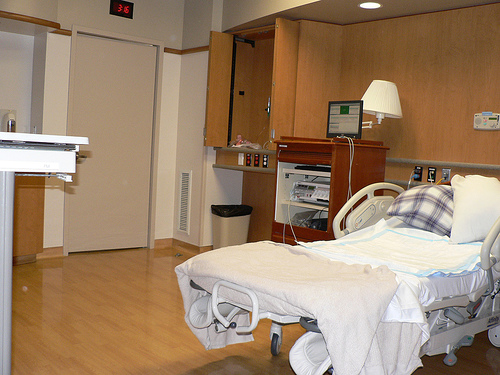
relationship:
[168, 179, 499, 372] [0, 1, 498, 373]
bed in room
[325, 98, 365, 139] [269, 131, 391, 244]
monitor on cabinet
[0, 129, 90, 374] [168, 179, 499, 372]
table for bed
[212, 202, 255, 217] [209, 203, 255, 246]
liner in trash can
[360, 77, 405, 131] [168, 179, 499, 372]
lamp beside bed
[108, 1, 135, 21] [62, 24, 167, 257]
clock above door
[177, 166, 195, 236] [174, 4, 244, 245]
air vent in wall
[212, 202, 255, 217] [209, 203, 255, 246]
garbage bag in garbage bin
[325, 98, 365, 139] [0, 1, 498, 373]
monitor in room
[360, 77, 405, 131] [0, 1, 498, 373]
lamp in room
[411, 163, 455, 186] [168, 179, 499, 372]
outlets behind bed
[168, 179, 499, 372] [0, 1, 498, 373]
bed for hospital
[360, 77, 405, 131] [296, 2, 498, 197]
lamp on wall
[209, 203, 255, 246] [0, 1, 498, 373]
trash can in room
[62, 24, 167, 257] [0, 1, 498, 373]
door to room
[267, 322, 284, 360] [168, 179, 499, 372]
wheel on bed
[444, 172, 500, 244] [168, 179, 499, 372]
pillow on bed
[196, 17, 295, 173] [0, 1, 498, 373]
storage in room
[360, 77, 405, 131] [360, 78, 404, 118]
lamp has shade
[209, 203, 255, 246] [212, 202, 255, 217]
trash can has bag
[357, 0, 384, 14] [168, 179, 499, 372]
light over bed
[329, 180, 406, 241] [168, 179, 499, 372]
rail on bed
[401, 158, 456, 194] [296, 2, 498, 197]
plugs and wires on wall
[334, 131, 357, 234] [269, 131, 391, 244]
wires hanging over table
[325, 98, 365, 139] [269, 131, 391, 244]
computer screen on table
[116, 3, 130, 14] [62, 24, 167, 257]
numbers above door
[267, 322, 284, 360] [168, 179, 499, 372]
wheel underneath bed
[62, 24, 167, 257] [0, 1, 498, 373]
door in room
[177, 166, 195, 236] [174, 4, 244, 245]
air vent on wall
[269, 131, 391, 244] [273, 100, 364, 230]
console for electronics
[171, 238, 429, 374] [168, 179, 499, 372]
blanket on bed